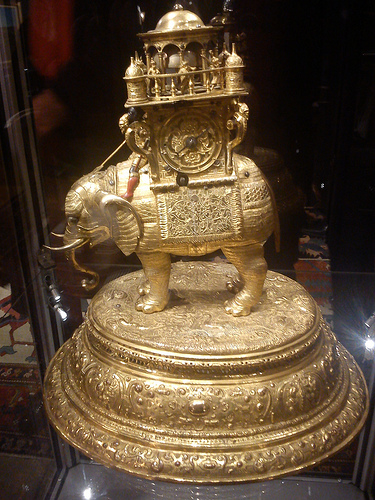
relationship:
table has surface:
[60, 309, 374, 496] [58, 450, 373, 497]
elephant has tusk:
[41, 1, 290, 319] [41, 238, 84, 249]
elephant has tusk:
[41, 1, 290, 319] [52, 226, 66, 240]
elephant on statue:
[41, 1, 290, 319] [31, 263, 374, 477]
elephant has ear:
[41, 1, 290, 319] [102, 196, 146, 258]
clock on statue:
[156, 108, 226, 182] [34, 1, 374, 479]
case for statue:
[4, 0, 374, 492] [34, 1, 374, 479]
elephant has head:
[41, 1, 290, 319] [60, 166, 144, 295]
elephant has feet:
[41, 1, 290, 319] [126, 249, 271, 318]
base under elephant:
[32, 259, 371, 482] [41, 1, 290, 319]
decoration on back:
[115, 1, 257, 194] [113, 149, 245, 208]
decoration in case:
[117, 1, 255, 191] [4, 0, 374, 492]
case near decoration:
[4, 0, 374, 492] [117, 1, 255, 191]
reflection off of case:
[241, 84, 310, 209] [4, 0, 374, 492]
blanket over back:
[153, 177, 242, 235] [113, 149, 245, 208]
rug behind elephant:
[4, 359, 48, 464] [41, 1, 290, 319]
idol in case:
[34, 1, 374, 479] [4, 0, 374, 492]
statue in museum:
[34, 1, 374, 479] [8, 0, 364, 492]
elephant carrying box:
[41, 1, 290, 319] [125, 0, 250, 188]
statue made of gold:
[34, 1, 374, 479] [37, 1, 374, 478]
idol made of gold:
[34, 1, 374, 479] [37, 1, 374, 478]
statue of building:
[34, 1, 374, 479] [127, 2, 252, 189]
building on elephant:
[127, 2, 252, 189] [41, 1, 290, 319]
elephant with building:
[41, 1, 290, 319] [127, 2, 252, 189]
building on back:
[127, 2, 252, 189] [113, 149, 245, 208]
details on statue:
[81, 0, 286, 260] [34, 1, 374, 479]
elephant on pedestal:
[41, 1, 290, 319] [32, 259, 371, 482]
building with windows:
[127, 2, 252, 189] [146, 42, 223, 93]